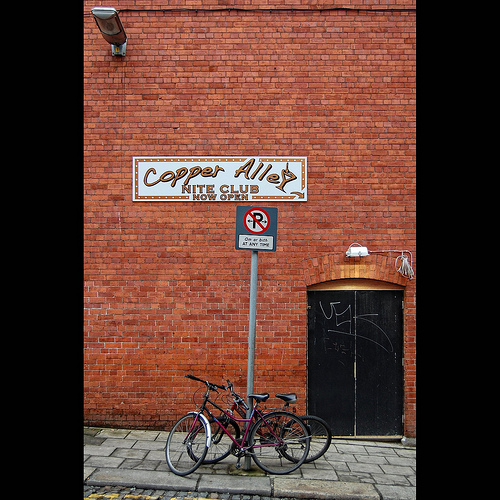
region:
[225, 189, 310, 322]
a sign on a pole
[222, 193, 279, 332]
a sign on a metal pole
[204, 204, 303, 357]
a street sign on a pole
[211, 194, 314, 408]
a street sign on a metal ple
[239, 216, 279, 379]
a pole with a sign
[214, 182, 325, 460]
a metal pole with a street sign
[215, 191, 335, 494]
a sign on the sidewalk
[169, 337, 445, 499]
bikes on the sidewalk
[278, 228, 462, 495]
a door on a building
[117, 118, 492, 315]
a building with business signs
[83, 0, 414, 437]
the brick building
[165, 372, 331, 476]
the bikes tied to the pole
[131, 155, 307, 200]
the sign on the building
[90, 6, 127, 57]
the light on the building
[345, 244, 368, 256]
the light on the building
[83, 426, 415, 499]
the sidewalk in front of the building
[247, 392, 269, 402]
the seat on the bike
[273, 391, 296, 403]
the seat on the bike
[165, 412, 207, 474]
the wheel on the bike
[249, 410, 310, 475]
the wheel on the bike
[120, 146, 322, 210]
Copper alley nite club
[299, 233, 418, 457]
graffitti written on the door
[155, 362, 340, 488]
two bikes chained to the pole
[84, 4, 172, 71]
security camera watching everyone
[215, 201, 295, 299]
grey white and red no parking sign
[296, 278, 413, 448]
black entrance back door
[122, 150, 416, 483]
two bikes chained in front of copper alley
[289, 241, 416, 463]
back door club light is on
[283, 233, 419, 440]
back door entrance for copper alley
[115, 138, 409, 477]
grand opening of copper alley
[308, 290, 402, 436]
the nightclub door has graffiti on it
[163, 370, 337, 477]
bicycles parked outside the nightclub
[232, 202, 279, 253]
there is no parking here at any time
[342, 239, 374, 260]
a light is positioned over the nightclub door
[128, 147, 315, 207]
a sign for the Copper Alley Nite Club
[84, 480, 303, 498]
the street is paved with cobblestones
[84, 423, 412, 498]
the sidewalk is made of stone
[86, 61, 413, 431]
this building is made of brick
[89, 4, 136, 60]
a street light attached to the building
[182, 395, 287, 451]
one of the bicycles is red